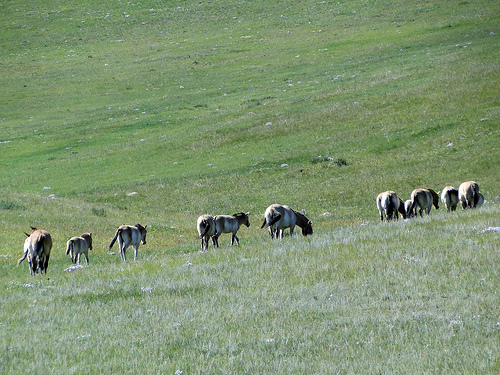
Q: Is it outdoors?
A: Yes, it is outdoors.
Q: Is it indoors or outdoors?
A: It is outdoors.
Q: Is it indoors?
A: No, it is outdoors.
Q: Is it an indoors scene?
A: No, it is outdoors.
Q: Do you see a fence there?
A: No, there are no fences.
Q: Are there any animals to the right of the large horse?
A: Yes, there is an animal to the right of the horse.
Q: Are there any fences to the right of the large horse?
A: No, there is an animal to the right of the horse.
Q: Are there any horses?
A: Yes, there is a horse.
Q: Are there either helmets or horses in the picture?
A: Yes, there is a horse.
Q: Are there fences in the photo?
A: No, there are no fences.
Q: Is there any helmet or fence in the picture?
A: No, there are no fences or helmets.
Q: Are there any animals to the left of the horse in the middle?
A: Yes, there is an animal to the left of the horse.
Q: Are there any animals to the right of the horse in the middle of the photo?
A: No, the animal is to the left of the horse.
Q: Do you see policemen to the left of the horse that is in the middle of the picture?
A: No, there is an animal to the left of the horse.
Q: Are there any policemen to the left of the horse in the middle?
A: No, there is an animal to the left of the horse.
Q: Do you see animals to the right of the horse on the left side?
A: Yes, there are animals to the right of the horse.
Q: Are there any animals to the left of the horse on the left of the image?
A: No, the animals are to the right of the horse.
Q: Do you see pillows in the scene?
A: No, there are no pillows.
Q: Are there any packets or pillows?
A: No, there are no pillows or packets.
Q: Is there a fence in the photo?
A: No, there are no fences.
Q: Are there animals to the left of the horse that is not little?
A: No, the animal is to the right of the horse.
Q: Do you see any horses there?
A: Yes, there is a horse.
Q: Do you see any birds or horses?
A: Yes, there is a horse.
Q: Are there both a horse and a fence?
A: No, there is a horse but no fences.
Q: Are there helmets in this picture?
A: No, there are no helmets.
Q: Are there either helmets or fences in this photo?
A: No, there are no helmets or fences.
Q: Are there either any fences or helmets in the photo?
A: No, there are no helmets or fences.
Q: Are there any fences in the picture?
A: No, there are no fences.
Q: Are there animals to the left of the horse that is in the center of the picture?
A: Yes, there is an animal to the left of the horse.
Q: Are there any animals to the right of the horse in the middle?
A: No, the animal is to the left of the horse.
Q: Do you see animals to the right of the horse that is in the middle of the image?
A: No, the animal is to the left of the horse.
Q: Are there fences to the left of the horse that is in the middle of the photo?
A: No, there is an animal to the left of the horse.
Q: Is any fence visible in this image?
A: No, there are no fences.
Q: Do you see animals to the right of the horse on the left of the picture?
A: Yes, there is an animal to the right of the horse.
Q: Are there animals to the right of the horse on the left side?
A: Yes, there is an animal to the right of the horse.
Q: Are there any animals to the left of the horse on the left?
A: No, the animal is to the right of the horse.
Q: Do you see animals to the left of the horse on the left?
A: No, the animal is to the right of the horse.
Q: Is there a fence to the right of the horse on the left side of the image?
A: No, there is an animal to the right of the horse.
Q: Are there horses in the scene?
A: Yes, there is a horse.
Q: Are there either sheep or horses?
A: Yes, there is a horse.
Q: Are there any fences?
A: No, there are no fences.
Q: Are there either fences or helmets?
A: No, there are no fences or helmets.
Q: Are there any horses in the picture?
A: Yes, there is a horse.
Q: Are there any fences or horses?
A: Yes, there is a horse.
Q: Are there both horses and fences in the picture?
A: No, there is a horse but no fences.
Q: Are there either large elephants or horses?
A: Yes, there is a large horse.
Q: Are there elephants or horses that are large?
A: Yes, the horse is large.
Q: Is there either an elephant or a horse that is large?
A: Yes, the horse is large.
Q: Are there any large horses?
A: Yes, there is a large horse.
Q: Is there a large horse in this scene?
A: Yes, there is a large horse.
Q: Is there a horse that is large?
A: Yes, there is a horse that is large.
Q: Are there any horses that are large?
A: Yes, there is a horse that is large.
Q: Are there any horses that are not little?
A: Yes, there is a large horse.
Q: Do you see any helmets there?
A: No, there are no helmets.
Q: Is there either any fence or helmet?
A: No, there are no helmets or fences.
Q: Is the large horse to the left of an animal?
A: Yes, the horse is to the left of an animal.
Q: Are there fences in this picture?
A: No, there are no fences.